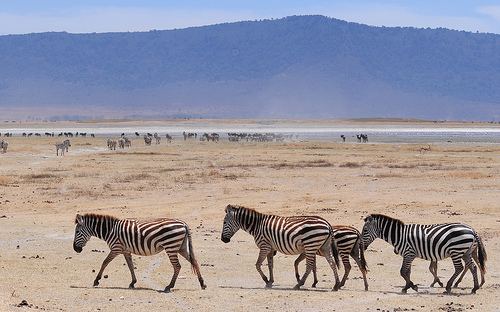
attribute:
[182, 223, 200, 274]
tail — long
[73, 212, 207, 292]
zebra — walking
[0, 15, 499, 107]
mountain — covered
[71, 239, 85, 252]
muzzle — black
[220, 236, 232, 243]
muzzle — black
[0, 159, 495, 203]
weeds — short, growing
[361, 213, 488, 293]
zebra — white, black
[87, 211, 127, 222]
mane — red, brown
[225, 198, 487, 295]
zebra — adult, baby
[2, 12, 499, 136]
mountain — background